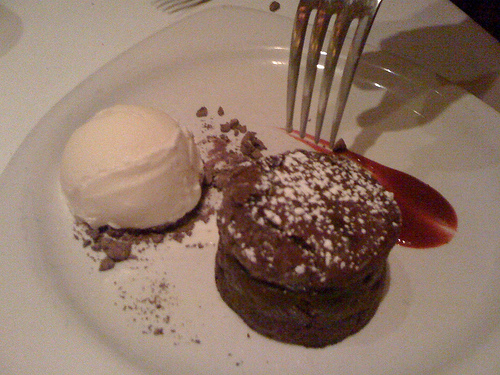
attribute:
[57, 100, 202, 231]
ice cream — white, vanilla 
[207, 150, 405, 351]
desert — type, brown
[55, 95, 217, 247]
desert — type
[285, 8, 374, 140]
fork — silver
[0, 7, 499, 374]
plate — glass, white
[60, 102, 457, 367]
dessert — very good looking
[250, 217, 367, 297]
brownie — brown 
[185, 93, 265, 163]
crumbs — choclate 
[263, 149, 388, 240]
powder — white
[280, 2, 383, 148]
fork — like this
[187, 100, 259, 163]
powder — brown, chocolate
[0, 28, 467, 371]
plate — round, white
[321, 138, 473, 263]
sauce — red, yummy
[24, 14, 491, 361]
plate — white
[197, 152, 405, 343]
brownie — chocolate